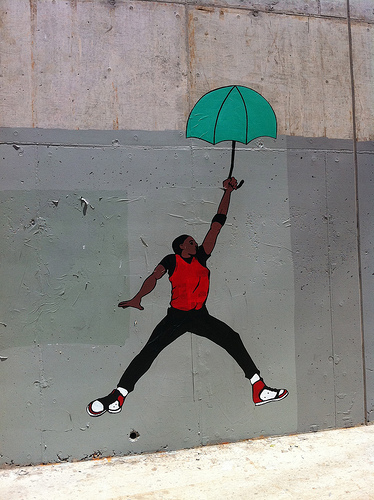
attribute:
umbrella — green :
[184, 84, 280, 144]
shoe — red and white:
[246, 377, 289, 408]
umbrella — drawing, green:
[184, 84, 278, 191]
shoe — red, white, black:
[222, 346, 321, 429]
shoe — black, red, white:
[63, 382, 139, 421]